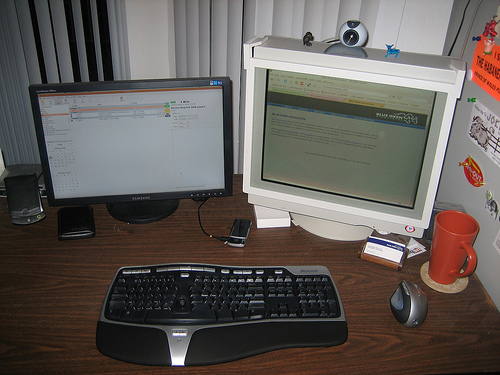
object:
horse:
[381, 41, 403, 59]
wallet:
[56, 200, 98, 240]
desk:
[8, 340, 82, 367]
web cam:
[322, 19, 373, 57]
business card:
[362, 234, 402, 263]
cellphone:
[223, 213, 253, 247]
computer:
[27, 31, 474, 368]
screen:
[161, 116, 224, 198]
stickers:
[462, 155, 484, 186]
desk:
[411, 341, 499, 375]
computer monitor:
[244, 30, 469, 244]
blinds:
[1, 4, 235, 74]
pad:
[252, 204, 291, 229]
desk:
[31, 257, 87, 340]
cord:
[188, 197, 224, 242]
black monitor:
[37, 76, 237, 224]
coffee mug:
[428, 210, 480, 285]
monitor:
[242, 32, 468, 243]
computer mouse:
[390, 281, 430, 327]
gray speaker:
[3, 172, 45, 224]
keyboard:
[96, 262, 344, 371]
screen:
[173, 163, 241, 200]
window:
[16, 13, 130, 103]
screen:
[253, 63, 326, 141]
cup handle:
[456, 243, 478, 278]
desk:
[285, 351, 314, 365]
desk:
[88, 241, 159, 257]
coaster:
[421, 284, 462, 293]